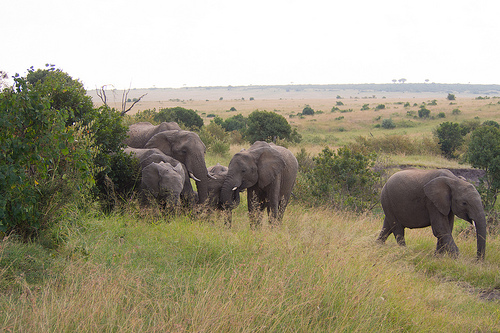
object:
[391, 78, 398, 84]
trees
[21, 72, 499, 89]
distant horizon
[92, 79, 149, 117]
tree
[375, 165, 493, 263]
elephant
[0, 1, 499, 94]
sky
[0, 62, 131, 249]
bushes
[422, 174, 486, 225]
head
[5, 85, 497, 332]
ground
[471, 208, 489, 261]
trunk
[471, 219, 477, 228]
tusk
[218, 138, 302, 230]
elephants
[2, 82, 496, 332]
grass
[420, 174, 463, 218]
ears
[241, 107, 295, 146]
plants